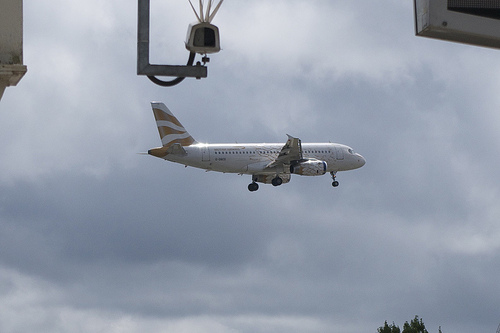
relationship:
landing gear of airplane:
[327, 172, 343, 188] [135, 98, 368, 195]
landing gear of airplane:
[268, 175, 285, 189] [135, 98, 368, 195]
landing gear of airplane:
[246, 179, 257, 192] [135, 98, 368, 195]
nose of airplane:
[355, 152, 367, 169] [135, 98, 368, 195]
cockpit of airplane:
[344, 145, 354, 159] [135, 98, 368, 195]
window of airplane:
[257, 148, 287, 157] [135, 98, 368, 195]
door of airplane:
[199, 144, 212, 164] [135, 98, 368, 195]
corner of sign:
[412, 14, 434, 40] [409, 1, 499, 55]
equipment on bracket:
[180, 0, 231, 62] [134, 1, 209, 82]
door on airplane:
[199, 144, 212, 164] [135, 98, 368, 195]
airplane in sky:
[135, 98, 368, 195] [1, 1, 500, 333]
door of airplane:
[331, 145, 349, 165] [135, 98, 368, 195]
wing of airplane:
[264, 133, 307, 171] [135, 98, 368, 195]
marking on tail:
[146, 107, 201, 160] [146, 100, 202, 146]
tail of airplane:
[146, 100, 202, 146] [135, 98, 368, 195]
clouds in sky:
[47, 2, 498, 94] [1, 1, 500, 333]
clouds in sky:
[5, 211, 498, 306] [1, 1, 500, 333]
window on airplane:
[257, 148, 287, 157] [135, 98, 368, 195]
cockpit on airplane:
[344, 145, 354, 159] [135, 98, 368, 195]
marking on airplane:
[146, 107, 201, 160] [135, 98, 368, 195]